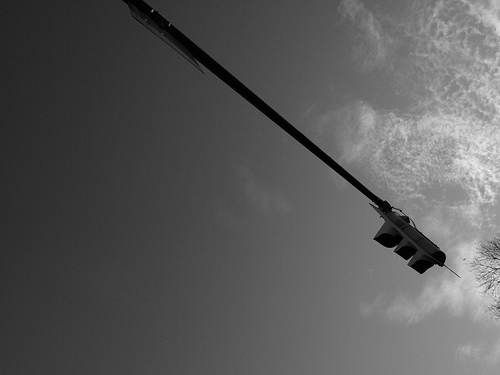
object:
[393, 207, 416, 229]
wire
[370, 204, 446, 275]
traffic signal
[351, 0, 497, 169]
sky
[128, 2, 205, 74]
street sign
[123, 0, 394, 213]
pole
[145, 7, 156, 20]
bracket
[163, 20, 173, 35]
bracket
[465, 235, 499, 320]
tree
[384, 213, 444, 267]
bump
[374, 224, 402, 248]
light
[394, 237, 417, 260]
light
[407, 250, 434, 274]
light